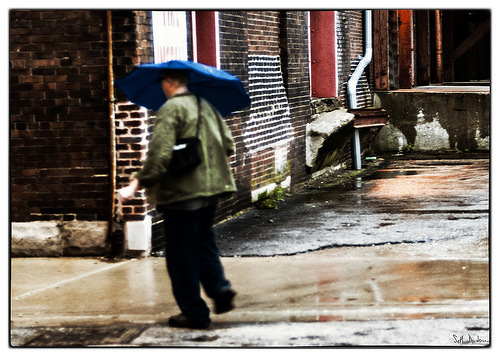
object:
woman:
[127, 65, 240, 325]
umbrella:
[121, 59, 251, 117]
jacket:
[132, 92, 240, 195]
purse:
[163, 135, 202, 166]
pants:
[163, 192, 240, 316]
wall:
[8, 10, 141, 220]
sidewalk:
[286, 257, 366, 297]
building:
[12, 9, 455, 259]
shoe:
[167, 307, 214, 331]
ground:
[0, 198, 490, 333]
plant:
[260, 157, 382, 208]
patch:
[408, 108, 450, 150]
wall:
[135, 10, 427, 251]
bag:
[163, 88, 206, 173]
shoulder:
[156, 94, 189, 117]